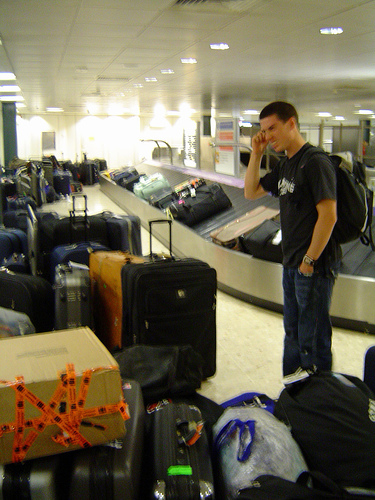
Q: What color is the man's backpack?
A: Black.